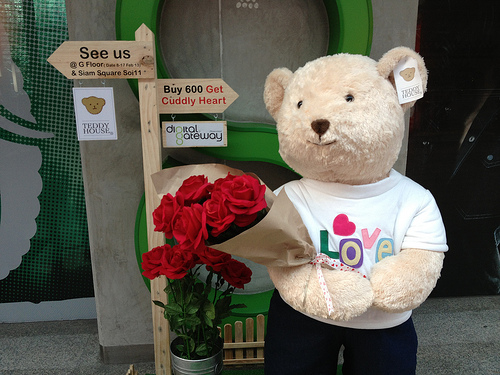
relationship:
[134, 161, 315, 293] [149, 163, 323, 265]
flowers in paper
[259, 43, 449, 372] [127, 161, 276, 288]
bear holding flowers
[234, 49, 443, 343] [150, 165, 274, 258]
bear holding flowers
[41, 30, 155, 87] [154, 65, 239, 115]
sign shape of left arrow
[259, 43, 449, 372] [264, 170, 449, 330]
bear in shirt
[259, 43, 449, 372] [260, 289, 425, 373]
bear in pants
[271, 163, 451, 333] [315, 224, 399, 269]
shirt has love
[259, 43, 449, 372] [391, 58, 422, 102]
bear has tag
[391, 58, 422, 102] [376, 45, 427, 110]
tag on ear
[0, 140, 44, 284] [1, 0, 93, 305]
paint on window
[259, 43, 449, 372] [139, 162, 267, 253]
bear holding roses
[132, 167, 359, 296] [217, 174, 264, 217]
bouquet of flower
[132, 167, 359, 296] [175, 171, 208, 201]
bouquet of flower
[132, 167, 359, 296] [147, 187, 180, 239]
bouquet of flower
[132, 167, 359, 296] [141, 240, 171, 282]
bouquet of flower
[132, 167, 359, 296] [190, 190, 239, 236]
bouquet of flower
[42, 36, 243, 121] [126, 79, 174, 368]
arrows on post